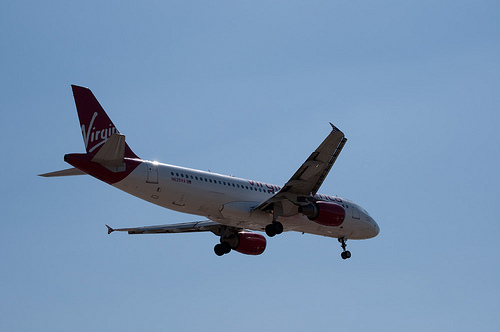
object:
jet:
[35, 84, 382, 261]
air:
[1, 2, 499, 331]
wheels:
[264, 220, 284, 237]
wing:
[255, 121, 347, 217]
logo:
[80, 111, 119, 154]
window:
[225, 181, 237, 188]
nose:
[367, 214, 381, 239]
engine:
[306, 202, 346, 227]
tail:
[63, 153, 92, 171]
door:
[146, 164, 158, 183]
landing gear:
[266, 206, 283, 238]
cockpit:
[358, 211, 371, 217]